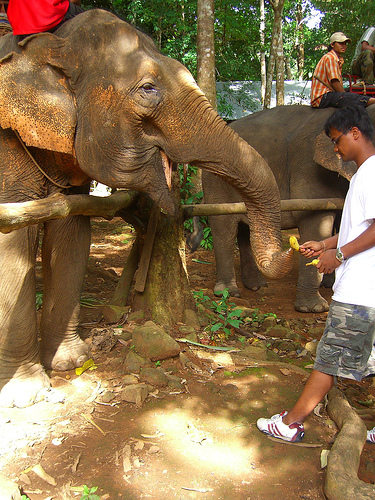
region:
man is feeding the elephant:
[70, 72, 373, 339]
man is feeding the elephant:
[85, 58, 370, 279]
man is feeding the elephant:
[88, 70, 366, 293]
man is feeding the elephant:
[109, 81, 372, 308]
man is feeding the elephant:
[109, 83, 367, 326]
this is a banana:
[282, 230, 310, 257]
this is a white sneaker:
[222, 400, 320, 462]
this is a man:
[256, 109, 374, 444]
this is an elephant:
[4, 4, 297, 372]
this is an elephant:
[196, 85, 361, 314]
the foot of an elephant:
[202, 193, 246, 298]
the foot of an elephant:
[290, 210, 333, 320]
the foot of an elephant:
[24, 196, 108, 374]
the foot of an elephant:
[1, 227, 56, 411]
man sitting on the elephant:
[207, 23, 373, 188]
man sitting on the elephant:
[261, 17, 372, 188]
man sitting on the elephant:
[257, 10, 371, 172]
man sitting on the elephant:
[235, 22, 364, 166]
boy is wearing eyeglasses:
[310, 100, 365, 192]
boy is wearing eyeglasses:
[288, 83, 373, 188]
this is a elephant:
[12, 15, 360, 395]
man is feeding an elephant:
[3, 6, 372, 451]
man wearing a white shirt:
[316, 155, 370, 336]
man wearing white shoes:
[239, 402, 305, 443]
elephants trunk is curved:
[147, 76, 327, 292]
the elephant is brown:
[13, 13, 339, 404]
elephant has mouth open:
[130, 120, 217, 245]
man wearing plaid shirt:
[297, 45, 358, 133]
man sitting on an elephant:
[190, 27, 368, 314]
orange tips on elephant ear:
[6, 68, 106, 199]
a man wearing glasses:
[326, 129, 345, 158]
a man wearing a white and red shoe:
[256, 410, 310, 441]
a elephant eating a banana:
[0, 5, 303, 280]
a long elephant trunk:
[187, 67, 300, 281]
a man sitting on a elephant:
[306, 28, 356, 113]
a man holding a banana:
[290, 235, 313, 253]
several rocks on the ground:
[113, 317, 182, 454]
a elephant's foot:
[295, 286, 331, 312]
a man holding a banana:
[307, 250, 335, 274]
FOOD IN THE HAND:
[290, 235, 294, 252]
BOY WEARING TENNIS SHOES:
[258, 419, 299, 436]